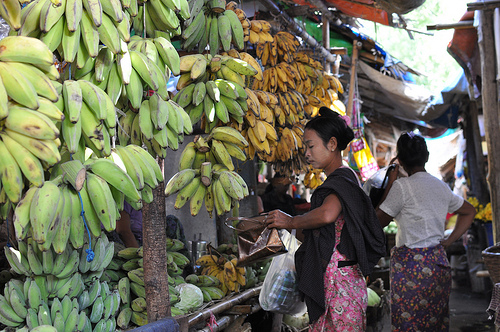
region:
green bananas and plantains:
[0, 36, 142, 328]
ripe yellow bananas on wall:
[243, 18, 371, 207]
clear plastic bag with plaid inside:
[264, 249, 317, 315]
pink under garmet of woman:
[318, 237, 407, 330]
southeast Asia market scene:
[21, 13, 478, 328]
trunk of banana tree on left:
[136, 147, 179, 327]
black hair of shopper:
[387, 126, 437, 174]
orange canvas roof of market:
[351, 2, 406, 39]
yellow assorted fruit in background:
[466, 197, 497, 229]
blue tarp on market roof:
[368, 44, 425, 98]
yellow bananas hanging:
[231, 10, 346, 165]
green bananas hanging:
[1, 0, 245, 258]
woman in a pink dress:
[237, 106, 379, 327]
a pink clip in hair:
[335, 110, 350, 126]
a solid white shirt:
[380, 170, 462, 247]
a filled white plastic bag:
[257, 225, 300, 311]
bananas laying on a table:
[0, 235, 250, 325]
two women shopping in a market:
[240, 100, 475, 326]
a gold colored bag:
[230, 210, 280, 263]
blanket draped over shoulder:
[296, 167, 387, 325]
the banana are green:
[70, 36, 225, 166]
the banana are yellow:
[70, 65, 245, 190]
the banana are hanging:
[80, 40, 280, 190]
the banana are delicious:
[60, 45, 245, 190]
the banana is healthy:
[50, 35, 275, 190]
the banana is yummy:
[35, 45, 225, 190]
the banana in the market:
[55, 45, 245, 190]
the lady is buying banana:
[90, 50, 270, 200]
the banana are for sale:
[75, 65, 245, 171]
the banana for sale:
[97, 47, 213, 153]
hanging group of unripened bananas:
[161, 153, 256, 223]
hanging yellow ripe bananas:
[260, 54, 310, 104]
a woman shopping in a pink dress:
[238, 98, 386, 328]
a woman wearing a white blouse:
[361, 121, 468, 328]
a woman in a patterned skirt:
[367, 120, 469, 330]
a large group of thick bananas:
[161, 158, 251, 223]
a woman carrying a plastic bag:
[231, 106, 411, 328]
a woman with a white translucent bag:
[231, 100, 378, 330]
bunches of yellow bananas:
[226, 3, 306, 166]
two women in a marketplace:
[223, 93, 478, 329]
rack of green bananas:
[19, 42, 227, 243]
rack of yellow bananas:
[221, 33, 346, 166]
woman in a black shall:
[246, 100, 403, 322]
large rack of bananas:
[15, 24, 367, 296]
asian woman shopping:
[246, 106, 418, 311]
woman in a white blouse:
[379, 118, 472, 318]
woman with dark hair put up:
[280, 87, 385, 212]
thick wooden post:
[120, 37, 188, 317]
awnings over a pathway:
[310, 2, 486, 218]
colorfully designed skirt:
[365, 228, 473, 328]